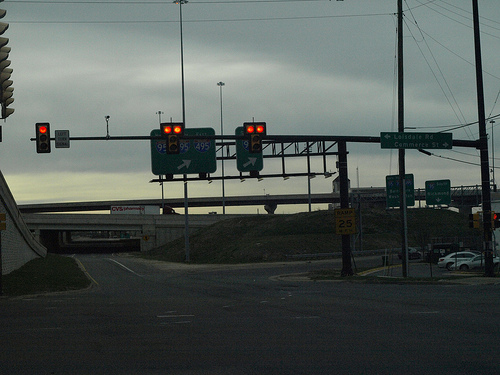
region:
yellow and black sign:
[325, 204, 359, 240]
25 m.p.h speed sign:
[325, 199, 361, 244]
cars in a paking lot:
[430, 239, 493, 286]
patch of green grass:
[28, 252, 68, 295]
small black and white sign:
[50, 130, 73, 167]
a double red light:
[127, 121, 192, 167]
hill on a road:
[179, 206, 296, 312]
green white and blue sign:
[132, 130, 214, 203]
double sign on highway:
[349, 160, 466, 230]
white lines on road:
[115, 294, 195, 366]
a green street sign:
[376, 127, 462, 153]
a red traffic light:
[33, 121, 52, 141]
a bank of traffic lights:
[30, 115, 55, 161]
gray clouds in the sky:
[0, 0, 499, 217]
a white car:
[434, 244, 485, 272]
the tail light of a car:
[435, 254, 447, 266]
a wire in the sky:
[0, 0, 397, 39]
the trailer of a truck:
[106, 200, 161, 221]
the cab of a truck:
[157, 201, 181, 221]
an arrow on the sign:
[381, 130, 394, 141]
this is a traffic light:
[31, 121, 52, 158]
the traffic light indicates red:
[37, 119, 51, 153]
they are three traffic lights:
[30, 114, 270, 159]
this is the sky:
[44, 20, 154, 90]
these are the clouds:
[231, 53, 277, 98]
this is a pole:
[466, 5, 495, 110]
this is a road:
[118, 277, 207, 364]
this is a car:
[445, 246, 468, 262]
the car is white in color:
[444, 255, 449, 260]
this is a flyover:
[56, 209, 146, 230]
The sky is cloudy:
[1, 1, 498, 186]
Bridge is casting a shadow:
[61, 233, 146, 259]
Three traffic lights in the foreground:
[14, 117, 282, 167]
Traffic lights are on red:
[31, 108, 271, 176]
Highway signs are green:
[146, 117, 273, 187]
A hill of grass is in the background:
[158, 203, 478, 269]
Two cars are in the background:
[428, 236, 497, 280]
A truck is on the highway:
[105, 196, 180, 221]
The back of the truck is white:
[107, 193, 185, 228]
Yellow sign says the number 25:
[331, 200, 366, 244]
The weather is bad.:
[43, 12, 414, 101]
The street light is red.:
[29, 117, 294, 154]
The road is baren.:
[80, 242, 255, 367]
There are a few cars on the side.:
[389, 230, 493, 286]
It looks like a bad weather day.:
[25, 54, 497, 344]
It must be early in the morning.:
[18, 44, 425, 354]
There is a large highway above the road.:
[53, 185, 498, 233]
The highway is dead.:
[35, 182, 482, 273]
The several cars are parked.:
[368, 215, 498, 292]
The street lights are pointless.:
[25, 114, 342, 172]